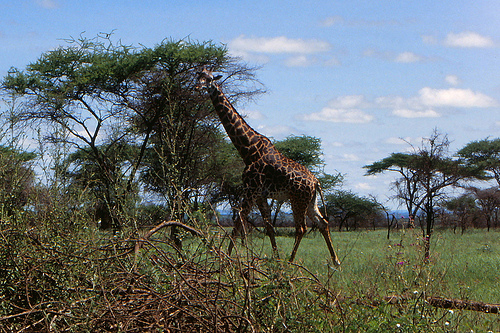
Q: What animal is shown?
A: A giraffe.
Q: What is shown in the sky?
A: Clouds.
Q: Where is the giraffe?
A: Field.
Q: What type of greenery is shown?
A: Trees.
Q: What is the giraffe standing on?
A: Grass.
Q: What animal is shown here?
A: Giraffe.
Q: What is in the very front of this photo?
A: Branches.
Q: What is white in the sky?
A: Clouds.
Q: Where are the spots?
A: On the giraffe.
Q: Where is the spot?
A: On the giraffe.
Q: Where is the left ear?
A: On the giraffe.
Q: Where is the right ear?
A: On the giraffe.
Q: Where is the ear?
A: On the giraffe.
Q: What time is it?
A: Afternoon.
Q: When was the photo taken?
A: During the daytime.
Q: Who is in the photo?
A: No people.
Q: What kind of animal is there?
A: Giraffe.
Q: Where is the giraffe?
A: In the grass.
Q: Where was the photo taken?
A: In the wild.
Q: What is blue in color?
A: The sky.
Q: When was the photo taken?
A: Daytime.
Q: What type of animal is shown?
A: Giraffe.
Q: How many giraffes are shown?
A: One.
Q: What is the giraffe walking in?
A: Grass.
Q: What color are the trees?
A: Green.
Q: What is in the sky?
A: Clouds.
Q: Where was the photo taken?
A: In the safari.